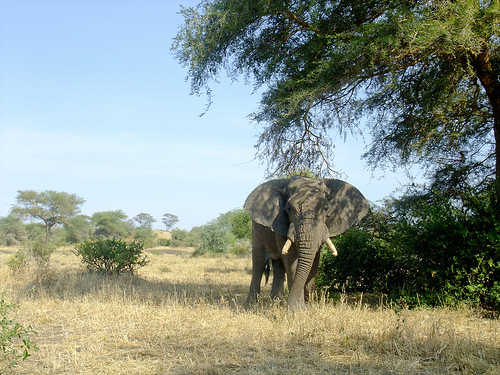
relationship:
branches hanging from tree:
[317, 16, 438, 112] [70, 232, 155, 297]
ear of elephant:
[238, 164, 278, 225] [222, 173, 372, 308]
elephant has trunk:
[222, 173, 372, 308] [290, 229, 322, 309]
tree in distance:
[70, 232, 155, 297] [3, 203, 159, 303]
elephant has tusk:
[222, 173, 372, 308] [272, 227, 297, 266]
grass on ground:
[118, 293, 220, 356] [115, 326, 295, 347]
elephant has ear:
[222, 173, 372, 308] [238, 164, 278, 225]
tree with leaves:
[70, 232, 155, 297] [78, 236, 139, 263]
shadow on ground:
[152, 292, 196, 303] [115, 326, 295, 347]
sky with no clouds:
[26, 26, 151, 160] [64, 86, 134, 150]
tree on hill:
[70, 232, 155, 297] [65, 208, 137, 236]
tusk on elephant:
[279, 233, 293, 256] [222, 173, 372, 308]